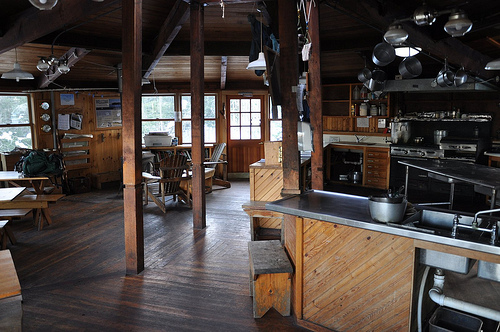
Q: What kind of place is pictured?
A: It is a restaurant.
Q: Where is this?
A: This is at the restaurant.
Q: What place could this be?
A: It is a restaurant.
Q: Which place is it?
A: It is a restaurant.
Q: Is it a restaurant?
A: Yes, it is a restaurant.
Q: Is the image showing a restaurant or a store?
A: It is showing a restaurant.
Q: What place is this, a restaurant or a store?
A: It is a restaurant.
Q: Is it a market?
A: No, it is a restaurant.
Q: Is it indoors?
A: Yes, it is indoors.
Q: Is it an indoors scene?
A: Yes, it is indoors.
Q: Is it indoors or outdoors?
A: It is indoors.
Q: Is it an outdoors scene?
A: No, it is indoors.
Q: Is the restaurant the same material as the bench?
A: Yes, both the restaurant and the bench are made of wood.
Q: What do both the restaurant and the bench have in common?
A: The material, both the restaurant and the bench are wooden.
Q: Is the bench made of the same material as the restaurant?
A: Yes, both the bench and the restaurant are made of wood.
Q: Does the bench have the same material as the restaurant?
A: Yes, both the bench and the restaurant are made of wood.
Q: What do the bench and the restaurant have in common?
A: The material, both the bench and the restaurant are wooden.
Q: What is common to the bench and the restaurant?
A: The material, both the bench and the restaurant are wooden.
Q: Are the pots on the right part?
A: Yes, the pots are on the right of the image.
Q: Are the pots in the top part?
A: Yes, the pots are in the top of the image.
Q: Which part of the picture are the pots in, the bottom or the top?
A: The pots are in the top of the image.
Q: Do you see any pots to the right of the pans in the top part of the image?
A: Yes, there are pots to the right of the pans.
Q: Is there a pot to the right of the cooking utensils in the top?
A: Yes, there are pots to the right of the pans.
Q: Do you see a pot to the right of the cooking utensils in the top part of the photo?
A: Yes, there are pots to the right of the pans.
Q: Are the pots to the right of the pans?
A: Yes, the pots are to the right of the pans.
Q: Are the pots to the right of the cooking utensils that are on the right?
A: Yes, the pots are to the right of the pans.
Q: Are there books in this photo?
A: No, there are no books.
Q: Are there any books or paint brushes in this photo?
A: No, there are no books or paint brushes.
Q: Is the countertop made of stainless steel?
A: Yes, the countertop is made of stainless steel.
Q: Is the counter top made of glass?
A: No, the counter top is made of stainless steel.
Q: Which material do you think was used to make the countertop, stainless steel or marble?
A: The countertop is made of stainless steel.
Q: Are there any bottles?
A: No, there are no bottles.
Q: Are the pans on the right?
A: Yes, the pans are on the right of the image.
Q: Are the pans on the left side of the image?
A: No, the pans are on the right of the image.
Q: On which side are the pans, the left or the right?
A: The pans are on the right of the image.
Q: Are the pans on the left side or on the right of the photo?
A: The pans are on the right of the image.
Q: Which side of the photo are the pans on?
A: The pans are on the right of the image.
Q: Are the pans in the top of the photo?
A: Yes, the pans are in the top of the image.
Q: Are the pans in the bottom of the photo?
A: No, the pans are in the top of the image.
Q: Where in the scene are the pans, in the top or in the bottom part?
A: The pans are in the top of the image.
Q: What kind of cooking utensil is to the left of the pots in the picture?
A: The cooking utensils are pans.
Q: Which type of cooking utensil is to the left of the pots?
A: The cooking utensils are pans.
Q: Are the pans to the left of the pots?
A: Yes, the pans are to the left of the pots.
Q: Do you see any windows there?
A: Yes, there is a window.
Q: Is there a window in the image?
A: Yes, there is a window.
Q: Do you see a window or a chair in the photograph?
A: Yes, there is a window.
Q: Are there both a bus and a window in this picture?
A: No, there is a window but no buses.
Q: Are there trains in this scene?
A: No, there are no trains.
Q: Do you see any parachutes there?
A: No, there are no parachutes.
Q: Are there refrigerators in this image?
A: No, there are no refrigerators.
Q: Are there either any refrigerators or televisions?
A: No, there are no refrigerators or televisions.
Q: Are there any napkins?
A: No, there are no napkins.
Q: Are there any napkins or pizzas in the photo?
A: No, there are no napkins or pizzas.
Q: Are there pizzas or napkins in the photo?
A: No, there are no napkins or pizzas.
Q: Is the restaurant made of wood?
A: Yes, the restaurant is made of wood.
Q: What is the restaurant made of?
A: The restaurant is made of wood.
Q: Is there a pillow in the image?
A: No, there are no pillows.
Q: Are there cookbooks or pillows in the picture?
A: No, there are no pillows or cookbooks.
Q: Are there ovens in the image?
A: Yes, there is an oven.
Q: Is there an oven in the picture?
A: Yes, there is an oven.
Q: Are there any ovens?
A: Yes, there is an oven.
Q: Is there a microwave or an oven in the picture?
A: Yes, there is an oven.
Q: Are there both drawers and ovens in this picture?
A: No, there is an oven but no drawers.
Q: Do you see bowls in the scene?
A: No, there are no bowls.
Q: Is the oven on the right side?
A: Yes, the oven is on the right of the image.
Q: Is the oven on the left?
A: No, the oven is on the right of the image.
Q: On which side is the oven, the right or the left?
A: The oven is on the right of the image.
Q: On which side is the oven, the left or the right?
A: The oven is on the right of the image.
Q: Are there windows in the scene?
A: Yes, there is a window.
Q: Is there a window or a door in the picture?
A: Yes, there is a window.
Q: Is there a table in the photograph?
A: Yes, there is a table.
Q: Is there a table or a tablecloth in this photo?
A: Yes, there is a table.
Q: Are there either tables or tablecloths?
A: Yes, there is a table.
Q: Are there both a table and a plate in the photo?
A: No, there is a table but no plates.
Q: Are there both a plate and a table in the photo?
A: No, there is a table but no plates.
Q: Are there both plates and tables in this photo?
A: No, there is a table but no plates.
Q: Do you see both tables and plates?
A: No, there is a table but no plates.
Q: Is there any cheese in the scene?
A: No, there is no cheese.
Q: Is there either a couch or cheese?
A: No, there are no cheese or couches.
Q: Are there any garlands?
A: No, there are no garlands.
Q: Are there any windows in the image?
A: Yes, there is a window.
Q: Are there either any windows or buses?
A: Yes, there is a window.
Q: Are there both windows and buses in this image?
A: No, there is a window but no buses.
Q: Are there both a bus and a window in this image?
A: No, there is a window but no buses.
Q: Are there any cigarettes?
A: No, there are no cigarettes.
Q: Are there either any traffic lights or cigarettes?
A: No, there are no cigarettes or traffic lights.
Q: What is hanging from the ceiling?
A: The light fixture is hanging from the ceiling.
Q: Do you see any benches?
A: Yes, there is a bench.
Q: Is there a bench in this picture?
A: Yes, there is a bench.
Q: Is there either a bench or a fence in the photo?
A: Yes, there is a bench.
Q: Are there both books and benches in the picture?
A: No, there is a bench but no books.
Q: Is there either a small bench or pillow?
A: Yes, there is a small bench.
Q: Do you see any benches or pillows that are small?
A: Yes, the bench is small.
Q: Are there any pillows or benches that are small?
A: Yes, the bench is small.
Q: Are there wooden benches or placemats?
A: Yes, there is a wood bench.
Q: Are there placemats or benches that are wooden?
A: Yes, the bench is wooden.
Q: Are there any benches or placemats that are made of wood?
A: Yes, the bench is made of wood.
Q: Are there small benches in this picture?
A: Yes, there is a small bench.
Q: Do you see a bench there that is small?
A: Yes, there is a bench that is small.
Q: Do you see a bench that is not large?
A: Yes, there is a small bench.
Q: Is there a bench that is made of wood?
A: Yes, there is a bench that is made of wood.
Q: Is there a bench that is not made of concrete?
A: Yes, there is a bench that is made of wood.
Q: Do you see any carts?
A: No, there are no carts.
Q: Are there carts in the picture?
A: No, there are no carts.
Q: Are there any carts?
A: No, there are no carts.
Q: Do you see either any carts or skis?
A: No, there are no carts or skis.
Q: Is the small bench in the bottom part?
A: Yes, the bench is in the bottom of the image.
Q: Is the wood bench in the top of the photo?
A: No, the bench is in the bottom of the image.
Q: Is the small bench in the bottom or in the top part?
A: The bench is in the bottom of the image.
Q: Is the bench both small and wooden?
A: Yes, the bench is small and wooden.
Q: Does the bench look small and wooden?
A: Yes, the bench is small and wooden.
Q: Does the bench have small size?
A: Yes, the bench is small.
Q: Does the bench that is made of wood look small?
A: Yes, the bench is small.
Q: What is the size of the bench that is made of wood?
A: The bench is small.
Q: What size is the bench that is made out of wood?
A: The bench is small.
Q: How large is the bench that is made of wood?
A: The bench is small.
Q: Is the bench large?
A: No, the bench is small.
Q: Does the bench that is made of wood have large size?
A: No, the bench is small.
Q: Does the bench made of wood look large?
A: No, the bench is small.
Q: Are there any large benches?
A: No, there is a bench but it is small.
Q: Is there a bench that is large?
A: No, there is a bench but it is small.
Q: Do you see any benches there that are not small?
A: No, there is a bench but it is small.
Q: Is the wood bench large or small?
A: The bench is small.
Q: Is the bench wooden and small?
A: Yes, the bench is wooden and small.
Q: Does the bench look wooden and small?
A: Yes, the bench is wooden and small.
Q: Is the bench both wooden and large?
A: No, the bench is wooden but small.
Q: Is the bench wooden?
A: Yes, the bench is wooden.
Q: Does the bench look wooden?
A: Yes, the bench is wooden.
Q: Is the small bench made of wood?
A: Yes, the bench is made of wood.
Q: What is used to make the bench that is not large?
A: The bench is made of wood.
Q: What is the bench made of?
A: The bench is made of wood.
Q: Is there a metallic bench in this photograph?
A: No, there is a bench but it is wooden.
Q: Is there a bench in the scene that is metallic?
A: No, there is a bench but it is wooden.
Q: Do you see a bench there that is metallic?
A: No, there is a bench but it is wooden.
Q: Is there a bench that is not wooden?
A: No, there is a bench but it is wooden.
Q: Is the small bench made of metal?
A: No, the bench is made of wood.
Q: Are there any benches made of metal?
A: No, there is a bench but it is made of wood.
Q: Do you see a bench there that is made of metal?
A: No, there is a bench but it is made of wood.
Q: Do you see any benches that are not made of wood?
A: No, there is a bench but it is made of wood.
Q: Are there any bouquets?
A: No, there are no bouquets.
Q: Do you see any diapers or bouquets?
A: No, there are no bouquets or diapers.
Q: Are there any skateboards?
A: No, there are no skateboards.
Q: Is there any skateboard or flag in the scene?
A: No, there are no skateboards or flags.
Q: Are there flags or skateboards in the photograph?
A: No, there are no skateboards or flags.